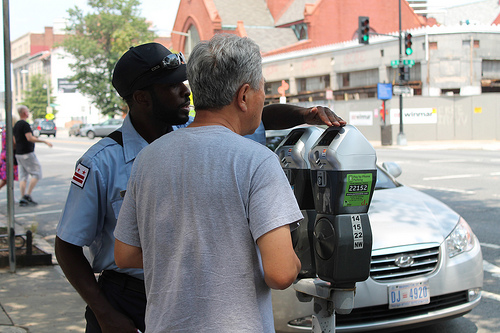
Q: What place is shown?
A: It is a street.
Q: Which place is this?
A: It is a street.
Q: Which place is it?
A: It is a street.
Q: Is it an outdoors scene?
A: Yes, it is outdoors.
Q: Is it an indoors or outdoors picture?
A: It is outdoors.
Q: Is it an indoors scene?
A: No, it is outdoors.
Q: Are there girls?
A: No, there are no girls.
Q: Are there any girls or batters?
A: No, there are no girls or batters.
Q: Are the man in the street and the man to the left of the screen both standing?
A: Yes, both the man and the man are standing.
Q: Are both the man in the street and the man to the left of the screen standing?
A: Yes, both the man and the man are standing.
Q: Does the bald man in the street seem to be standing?
A: Yes, the man is standing.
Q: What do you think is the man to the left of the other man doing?
A: The man is standing.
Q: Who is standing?
A: The man is standing.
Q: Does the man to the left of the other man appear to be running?
A: No, the man is standing.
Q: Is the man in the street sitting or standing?
A: The man is standing.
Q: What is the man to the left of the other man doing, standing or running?
A: The man is standing.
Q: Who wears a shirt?
A: The man wears a shirt.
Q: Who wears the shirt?
A: The man wears a shirt.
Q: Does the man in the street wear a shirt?
A: Yes, the man wears a shirt.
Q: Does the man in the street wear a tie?
A: No, the man wears a shirt.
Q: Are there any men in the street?
A: Yes, there is a man in the street.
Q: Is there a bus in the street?
A: No, there is a man in the street.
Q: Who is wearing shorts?
A: The man is wearing shorts.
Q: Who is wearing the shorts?
A: The man is wearing shorts.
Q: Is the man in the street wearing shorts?
A: Yes, the man is wearing shorts.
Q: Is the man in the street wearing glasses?
A: No, the man is wearing shorts.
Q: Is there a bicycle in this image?
A: No, there are no bicycles.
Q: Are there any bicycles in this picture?
A: No, there are no bicycles.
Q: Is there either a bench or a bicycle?
A: No, there are no bicycles or benches.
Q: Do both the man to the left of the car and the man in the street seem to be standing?
A: Yes, both the man and the man are standing.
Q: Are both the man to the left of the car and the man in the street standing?
A: Yes, both the man and the man are standing.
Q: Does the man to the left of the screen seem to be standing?
A: Yes, the man is standing.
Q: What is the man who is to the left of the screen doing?
A: The man is standing.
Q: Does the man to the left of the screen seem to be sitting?
A: No, the man is standing.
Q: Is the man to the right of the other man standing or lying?
A: The man is standing.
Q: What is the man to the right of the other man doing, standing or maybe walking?
A: The man is standing.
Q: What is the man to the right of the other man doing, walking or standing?
A: The man is standing.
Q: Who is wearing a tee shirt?
A: The man is wearing a tee shirt.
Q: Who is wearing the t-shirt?
A: The man is wearing a tee shirt.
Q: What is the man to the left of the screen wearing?
A: The man is wearing a t-shirt.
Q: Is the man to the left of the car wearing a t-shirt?
A: Yes, the man is wearing a t-shirt.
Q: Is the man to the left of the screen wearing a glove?
A: No, the man is wearing a t-shirt.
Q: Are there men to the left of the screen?
A: Yes, there is a man to the left of the screen.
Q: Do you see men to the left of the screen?
A: Yes, there is a man to the left of the screen.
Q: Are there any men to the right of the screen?
A: No, the man is to the left of the screen.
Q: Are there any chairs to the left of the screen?
A: No, there is a man to the left of the screen.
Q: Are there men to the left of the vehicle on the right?
A: Yes, there is a man to the left of the car.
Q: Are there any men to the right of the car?
A: No, the man is to the left of the car.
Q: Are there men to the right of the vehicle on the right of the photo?
A: No, the man is to the left of the car.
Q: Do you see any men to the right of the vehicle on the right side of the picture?
A: No, the man is to the left of the car.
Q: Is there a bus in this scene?
A: No, there are no buses.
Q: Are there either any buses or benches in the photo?
A: No, there are no buses or benches.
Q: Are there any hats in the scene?
A: Yes, there is a hat.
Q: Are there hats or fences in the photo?
A: Yes, there is a hat.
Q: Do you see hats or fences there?
A: Yes, there is a hat.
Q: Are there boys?
A: No, there are no boys.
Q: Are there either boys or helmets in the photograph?
A: No, there are no boys or helmets.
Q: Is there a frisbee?
A: No, there are no frisbees.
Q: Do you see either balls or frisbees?
A: No, there are no frisbees or balls.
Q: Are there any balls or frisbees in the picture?
A: No, there are no frisbees or balls.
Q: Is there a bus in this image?
A: No, there are no buses.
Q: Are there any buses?
A: No, there are no buses.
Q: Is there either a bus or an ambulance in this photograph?
A: No, there are no buses or ambulances.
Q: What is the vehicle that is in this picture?
A: The vehicle is a car.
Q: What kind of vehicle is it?
A: The vehicle is a car.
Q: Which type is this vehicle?
A: This is a car.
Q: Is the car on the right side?
A: Yes, the car is on the right of the image.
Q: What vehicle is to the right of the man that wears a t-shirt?
A: The vehicle is a car.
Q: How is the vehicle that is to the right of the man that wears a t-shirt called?
A: The vehicle is a car.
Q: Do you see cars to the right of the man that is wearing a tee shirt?
A: Yes, there is a car to the right of the man.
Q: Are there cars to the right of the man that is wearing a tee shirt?
A: Yes, there is a car to the right of the man.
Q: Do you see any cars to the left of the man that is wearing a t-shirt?
A: No, the car is to the right of the man.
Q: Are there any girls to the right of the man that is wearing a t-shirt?
A: No, there is a car to the right of the man.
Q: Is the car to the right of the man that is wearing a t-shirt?
A: Yes, the car is to the right of the man.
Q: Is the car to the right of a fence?
A: No, the car is to the right of the man.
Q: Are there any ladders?
A: No, there are no ladders.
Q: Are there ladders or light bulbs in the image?
A: No, there are no ladders or light bulbs.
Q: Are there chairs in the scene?
A: No, there are no chairs.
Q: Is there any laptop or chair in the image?
A: No, there are no chairs or laptops.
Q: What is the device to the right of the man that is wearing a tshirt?
A: The device is a screen.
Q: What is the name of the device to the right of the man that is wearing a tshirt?
A: The device is a screen.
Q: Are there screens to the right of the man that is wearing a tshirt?
A: Yes, there is a screen to the right of the man.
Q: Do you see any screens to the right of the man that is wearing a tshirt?
A: Yes, there is a screen to the right of the man.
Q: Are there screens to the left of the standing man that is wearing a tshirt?
A: No, the screen is to the right of the man.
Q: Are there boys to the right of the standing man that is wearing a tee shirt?
A: No, there is a screen to the right of the man.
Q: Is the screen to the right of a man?
A: Yes, the screen is to the right of a man.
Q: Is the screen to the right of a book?
A: No, the screen is to the right of a man.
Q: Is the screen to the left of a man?
A: No, the screen is to the right of a man.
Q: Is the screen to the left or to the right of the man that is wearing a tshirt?
A: The screen is to the right of the man.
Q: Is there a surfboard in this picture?
A: No, there are no surfboards.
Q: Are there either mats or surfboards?
A: No, there are no surfboards or mats.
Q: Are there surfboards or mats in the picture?
A: No, there are no surfboards or mats.